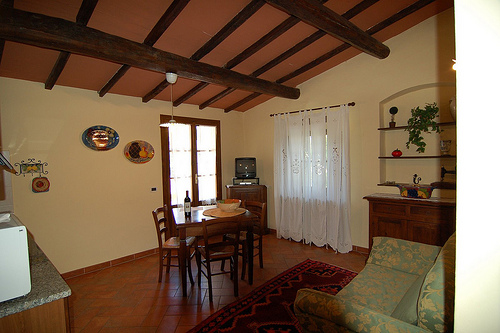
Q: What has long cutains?
A: A window.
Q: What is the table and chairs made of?
A: Wood.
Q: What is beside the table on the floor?
A: A rug.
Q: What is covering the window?
A: Curtains.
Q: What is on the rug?
A: Chair.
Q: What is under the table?
A: Chairs.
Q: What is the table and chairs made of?
A: Wood.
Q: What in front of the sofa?
A: Rug.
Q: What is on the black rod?
A: White curtain.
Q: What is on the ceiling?
A: Wooden beams.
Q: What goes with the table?
A: The chairs.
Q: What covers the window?
A: Curtain.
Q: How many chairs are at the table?
A: 4.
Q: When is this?
A: Afternoon.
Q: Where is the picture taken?
A: Dining room.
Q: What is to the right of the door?
A: Television.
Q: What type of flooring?
A: Ceramic tiles.